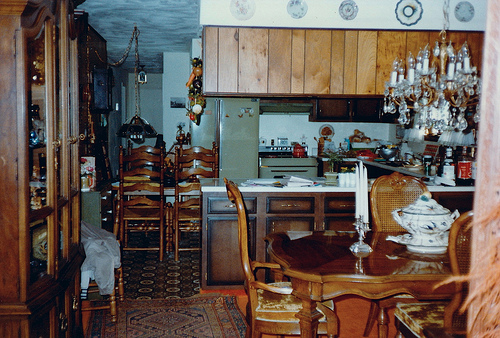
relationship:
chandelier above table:
[408, 72, 470, 108] [308, 246, 334, 283]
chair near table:
[246, 230, 249, 277] [308, 246, 334, 283]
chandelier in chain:
[408, 72, 470, 108] [441, 7, 449, 28]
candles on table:
[354, 169, 368, 244] [308, 246, 334, 283]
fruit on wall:
[191, 64, 201, 132] [214, 55, 240, 79]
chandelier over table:
[408, 72, 470, 108] [308, 246, 334, 283]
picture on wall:
[170, 96, 185, 106] [214, 55, 240, 79]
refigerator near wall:
[235, 119, 253, 135] [214, 55, 240, 79]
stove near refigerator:
[271, 157, 308, 172] [235, 119, 253, 135]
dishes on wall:
[227, 5, 478, 23] [214, 55, 240, 79]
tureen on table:
[412, 201, 439, 238] [308, 246, 334, 283]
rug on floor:
[185, 307, 223, 331] [160, 277, 174, 291]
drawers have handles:
[250, 203, 346, 213] [286, 203, 298, 208]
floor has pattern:
[160, 277, 174, 291] [170, 280, 176, 292]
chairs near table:
[130, 153, 197, 197] [308, 246, 334, 283]